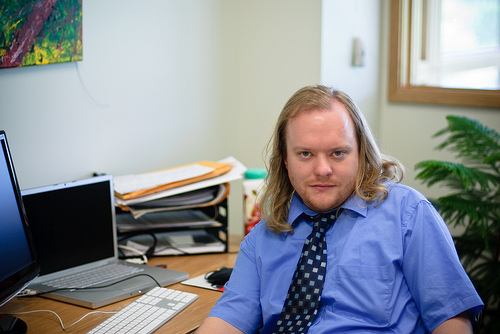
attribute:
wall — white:
[119, 34, 180, 81]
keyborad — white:
[94, 303, 208, 331]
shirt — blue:
[354, 232, 381, 285]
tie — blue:
[289, 248, 319, 311]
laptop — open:
[40, 167, 122, 306]